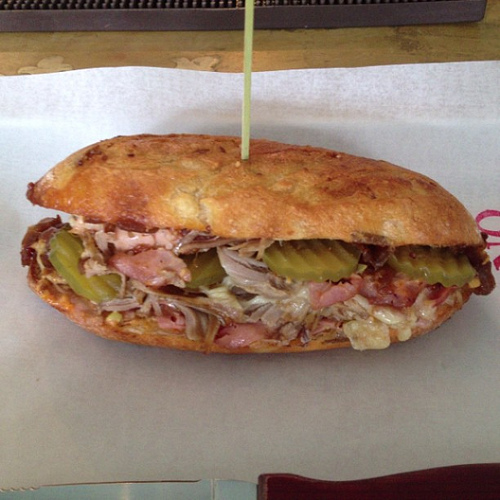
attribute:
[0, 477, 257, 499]
blade — sharp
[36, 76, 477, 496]
paper — white, wax, food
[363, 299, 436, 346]
cheese — melted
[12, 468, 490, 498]
knife — wood, metal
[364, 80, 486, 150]
sheet — white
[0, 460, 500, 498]
knife — silver, wood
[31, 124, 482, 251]
bread — toasted, bottom, top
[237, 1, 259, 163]
stick — small, skinny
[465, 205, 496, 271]
letters — red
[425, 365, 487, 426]
background — white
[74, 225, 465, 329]
meat — cold, cut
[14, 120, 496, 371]
bread — golden, brown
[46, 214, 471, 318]
pickles — crinkled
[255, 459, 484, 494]
handle — brown, wooden, knife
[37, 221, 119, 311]
pickle — green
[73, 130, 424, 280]
sandwich bun — toasted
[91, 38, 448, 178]
paper — white